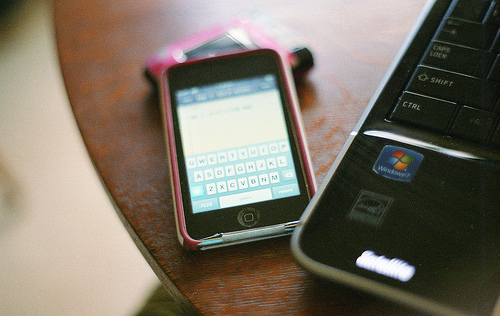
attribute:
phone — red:
[160, 46, 323, 252]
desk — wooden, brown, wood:
[52, 0, 499, 314]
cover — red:
[154, 44, 321, 253]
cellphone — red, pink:
[129, 12, 325, 92]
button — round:
[234, 205, 268, 226]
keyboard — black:
[391, 0, 500, 157]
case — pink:
[140, 20, 306, 84]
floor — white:
[2, 3, 161, 316]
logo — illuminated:
[346, 242, 416, 288]